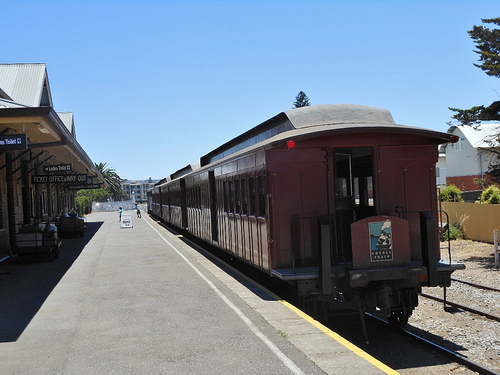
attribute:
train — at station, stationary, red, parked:
[153, 125, 453, 311]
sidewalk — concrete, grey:
[72, 195, 249, 374]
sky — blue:
[124, 28, 397, 111]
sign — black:
[118, 205, 127, 230]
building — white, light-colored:
[12, 76, 105, 268]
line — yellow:
[273, 296, 379, 373]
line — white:
[145, 217, 305, 375]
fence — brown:
[439, 199, 499, 241]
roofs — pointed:
[1, 63, 76, 134]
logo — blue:
[362, 226, 394, 260]